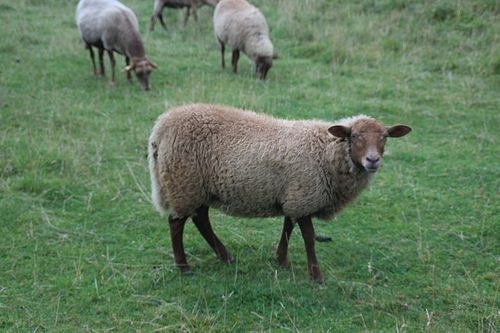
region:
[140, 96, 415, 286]
A sheep in grassy field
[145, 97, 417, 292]
A sheep in grassy field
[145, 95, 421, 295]
A sheep in grassy field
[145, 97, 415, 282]
A sheep in grassy field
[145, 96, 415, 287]
A sheep in grassy field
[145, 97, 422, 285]
Sheep looking at camera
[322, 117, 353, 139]
Ear of standing sheep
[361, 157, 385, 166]
Nose of standing sheep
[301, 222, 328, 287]
Leg of standing sheep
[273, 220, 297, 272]
Leg of standing sheep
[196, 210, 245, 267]
Leg of standing sheep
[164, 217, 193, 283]
Leg of standing sheep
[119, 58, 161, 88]
Head of grazing sheep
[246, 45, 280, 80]
Head of grazing sheep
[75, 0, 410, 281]
the animals on the grass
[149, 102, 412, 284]
the sheep standing on the grass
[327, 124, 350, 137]
the right ear on the sheep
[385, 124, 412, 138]
the left ear on the sheep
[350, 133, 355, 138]
the right eye on the sheep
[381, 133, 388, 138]
the left eye on the sheep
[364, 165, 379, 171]
the mouth on the sheep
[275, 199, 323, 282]
the front legs on the sheep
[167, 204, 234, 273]
the back legs on the sheep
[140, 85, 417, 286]
a brown sheep on green grass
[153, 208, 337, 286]
feet of sheep is dark brown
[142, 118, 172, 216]
tail of sheep is long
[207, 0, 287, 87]
a sheep is eating green grass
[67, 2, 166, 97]
a sheep is eating green grass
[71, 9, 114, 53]
the belly is bulky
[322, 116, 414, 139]
the ears of sheep are on sides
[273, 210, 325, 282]
front legs of sheep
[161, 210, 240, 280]
back legs of sheep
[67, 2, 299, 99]
two sheeps are eating grass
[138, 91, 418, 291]
A sheep in a grassy field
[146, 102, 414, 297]
An animal in a field.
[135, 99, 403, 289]
brown sheep in green pasture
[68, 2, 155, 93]
brown sheep in green pasture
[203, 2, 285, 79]
brown sheep in green pasture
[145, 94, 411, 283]
sheep in green pasture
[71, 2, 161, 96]
brown sheep grazing in green pasture